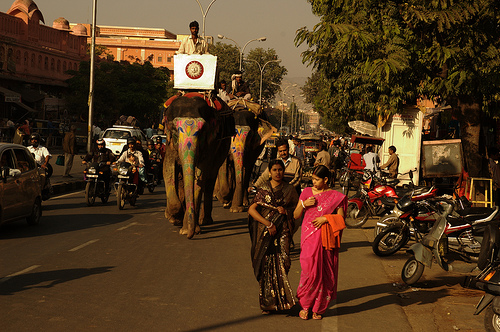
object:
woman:
[296, 162, 346, 323]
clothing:
[295, 186, 347, 312]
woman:
[247, 159, 303, 316]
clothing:
[247, 180, 304, 309]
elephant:
[162, 90, 237, 240]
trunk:
[173, 117, 205, 240]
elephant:
[212, 102, 278, 213]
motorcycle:
[399, 202, 500, 285]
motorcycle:
[372, 188, 489, 258]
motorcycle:
[341, 171, 442, 229]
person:
[112, 142, 145, 179]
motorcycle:
[109, 161, 147, 211]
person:
[81, 138, 117, 186]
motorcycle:
[79, 154, 114, 208]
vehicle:
[0, 142, 53, 227]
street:
[1, 182, 342, 330]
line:
[2, 208, 165, 281]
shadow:
[0, 265, 115, 296]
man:
[175, 20, 213, 54]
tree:
[291, 0, 498, 176]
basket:
[170, 50, 218, 92]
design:
[185, 59, 205, 79]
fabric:
[321, 213, 347, 251]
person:
[248, 139, 305, 198]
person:
[327, 140, 340, 162]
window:
[165, 56, 172, 63]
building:
[0, 0, 211, 96]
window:
[156, 55, 164, 63]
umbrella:
[347, 120, 377, 137]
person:
[291, 137, 305, 163]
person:
[377, 144, 401, 179]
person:
[312, 141, 332, 176]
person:
[363, 146, 381, 183]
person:
[123, 152, 143, 184]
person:
[62, 125, 78, 179]